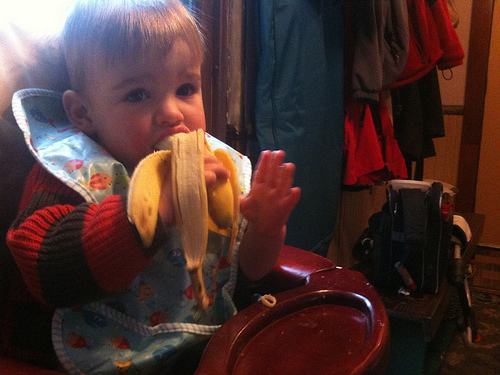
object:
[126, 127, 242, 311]
banana peel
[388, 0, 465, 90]
coats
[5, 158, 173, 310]
sweater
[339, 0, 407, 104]
brown coat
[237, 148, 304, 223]
hand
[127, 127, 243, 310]
banana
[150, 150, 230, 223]
hand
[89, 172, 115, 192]
goldfish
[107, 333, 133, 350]
goldfish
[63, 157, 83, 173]
goldfish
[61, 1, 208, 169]
head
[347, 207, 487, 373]
bench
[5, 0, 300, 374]
baby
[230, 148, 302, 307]
baby's arm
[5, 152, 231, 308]
arm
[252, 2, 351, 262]
bag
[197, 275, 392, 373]
tray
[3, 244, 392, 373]
highchair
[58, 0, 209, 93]
blonde hair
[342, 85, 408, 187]
garment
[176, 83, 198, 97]
eye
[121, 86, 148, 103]
eye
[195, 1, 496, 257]
wall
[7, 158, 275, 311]
sweater